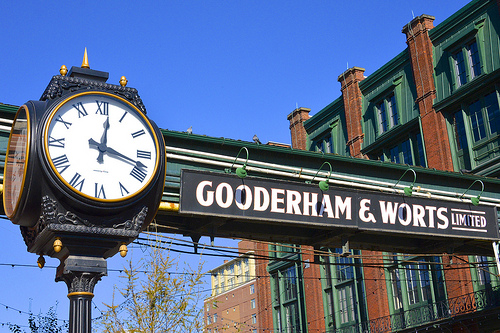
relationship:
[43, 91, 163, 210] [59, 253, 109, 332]
clock of pole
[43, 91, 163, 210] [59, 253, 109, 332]
clock on post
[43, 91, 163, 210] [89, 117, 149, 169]
clock has hands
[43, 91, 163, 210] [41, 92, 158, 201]
clock has face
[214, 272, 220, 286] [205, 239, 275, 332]
window on building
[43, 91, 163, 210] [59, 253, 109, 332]
clock on pole